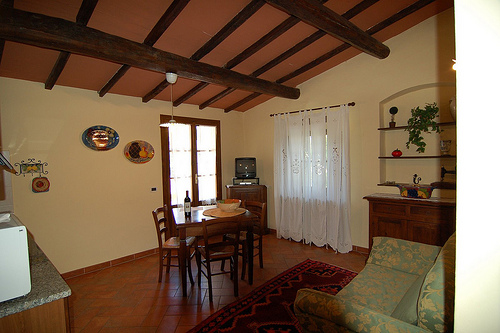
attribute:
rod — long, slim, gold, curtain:
[267, 100, 356, 117]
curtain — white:
[245, 107, 360, 263]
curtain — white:
[275, 105, 355, 255]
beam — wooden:
[74, 23, 346, 114]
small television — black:
[234, 154, 256, 181]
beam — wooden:
[3, 6, 300, 98]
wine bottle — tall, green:
[181, 192, 192, 219]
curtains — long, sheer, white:
[253, 103, 383, 254]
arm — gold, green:
[296, 287, 372, 332]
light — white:
[161, 71, 181, 135]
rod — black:
[267, 104, 351, 120]